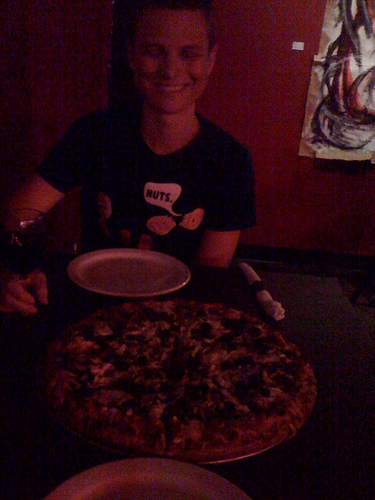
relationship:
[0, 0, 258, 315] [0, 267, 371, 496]
guy standing next to table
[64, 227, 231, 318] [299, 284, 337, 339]
plate sitting under table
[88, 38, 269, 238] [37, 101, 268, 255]
man has on tshirt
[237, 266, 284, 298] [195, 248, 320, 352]
ring around napkin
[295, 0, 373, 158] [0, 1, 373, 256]
paper on wall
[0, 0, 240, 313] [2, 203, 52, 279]
man holding glass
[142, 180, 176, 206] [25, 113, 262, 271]
writing on shirt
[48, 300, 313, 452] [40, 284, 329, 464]
cheese on pizza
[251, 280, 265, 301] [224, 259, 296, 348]
silverware on napkin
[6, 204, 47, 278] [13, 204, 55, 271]
wineglass filled with wine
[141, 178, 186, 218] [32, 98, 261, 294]
design on t shirt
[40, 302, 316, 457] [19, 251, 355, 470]
pizza on table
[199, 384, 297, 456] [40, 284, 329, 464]
crust on pizza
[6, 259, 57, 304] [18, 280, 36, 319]
hand holding wine stem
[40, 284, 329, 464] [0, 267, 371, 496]
pizza on table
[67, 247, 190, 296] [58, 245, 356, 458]
plate on table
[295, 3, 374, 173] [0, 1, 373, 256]
painting on wall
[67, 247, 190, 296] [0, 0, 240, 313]
plate in front of man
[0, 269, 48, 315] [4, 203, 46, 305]
hand holds glass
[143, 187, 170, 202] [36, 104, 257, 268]
word appears on shirt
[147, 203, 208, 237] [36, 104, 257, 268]
peanut on shirt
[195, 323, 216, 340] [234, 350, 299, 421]
sausage on pizza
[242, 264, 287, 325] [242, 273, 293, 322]
silverware wrapped in napkin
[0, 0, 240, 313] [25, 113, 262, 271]
man wearing shirt